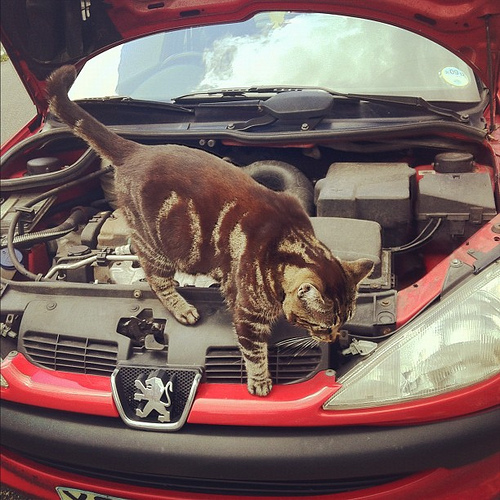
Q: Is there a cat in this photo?
A: Yes, there is a cat.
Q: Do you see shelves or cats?
A: Yes, there is a cat.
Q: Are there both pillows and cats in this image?
A: No, there is a cat but no pillows.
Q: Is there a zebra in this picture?
A: No, there are no zebras.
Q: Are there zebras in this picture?
A: No, there are no zebras.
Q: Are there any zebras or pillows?
A: No, there are no zebras or pillows.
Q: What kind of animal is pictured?
A: The animal is a cat.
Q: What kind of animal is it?
A: The animal is a cat.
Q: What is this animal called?
A: This is a cat.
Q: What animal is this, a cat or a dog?
A: This is a cat.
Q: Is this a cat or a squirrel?
A: This is a cat.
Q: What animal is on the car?
A: The animal is a cat.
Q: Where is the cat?
A: The cat is on the car.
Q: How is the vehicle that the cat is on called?
A: The vehicle is a car.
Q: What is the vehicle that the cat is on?
A: The vehicle is a car.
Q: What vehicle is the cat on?
A: The cat is on the car.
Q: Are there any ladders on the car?
A: No, there is a cat on the car.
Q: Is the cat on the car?
A: Yes, the cat is on the car.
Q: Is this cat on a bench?
A: No, the cat is on the car.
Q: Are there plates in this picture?
A: Yes, there is a plate.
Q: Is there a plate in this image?
A: Yes, there is a plate.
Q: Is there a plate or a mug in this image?
A: Yes, there is a plate.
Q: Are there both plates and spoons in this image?
A: No, there is a plate but no spoons.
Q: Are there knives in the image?
A: No, there are no knives.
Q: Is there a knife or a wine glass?
A: No, there are no knives or wine glasses.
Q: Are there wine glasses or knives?
A: No, there are no knives or wine glasses.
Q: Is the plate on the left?
A: Yes, the plate is on the left of the image.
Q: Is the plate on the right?
A: No, the plate is on the left of the image.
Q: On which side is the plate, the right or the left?
A: The plate is on the left of the image.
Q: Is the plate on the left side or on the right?
A: The plate is on the left of the image.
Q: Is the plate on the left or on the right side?
A: The plate is on the left of the image.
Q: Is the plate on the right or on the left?
A: The plate is on the left of the image.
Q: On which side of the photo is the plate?
A: The plate is on the left of the image.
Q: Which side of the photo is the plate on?
A: The plate is on the left of the image.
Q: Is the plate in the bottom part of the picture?
A: Yes, the plate is in the bottom of the image.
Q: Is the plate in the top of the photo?
A: No, the plate is in the bottom of the image.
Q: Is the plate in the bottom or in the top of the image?
A: The plate is in the bottom of the image.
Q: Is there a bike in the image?
A: No, there are no bikes.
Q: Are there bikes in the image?
A: No, there are no bikes.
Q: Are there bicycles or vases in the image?
A: No, there are no bicycles or vases.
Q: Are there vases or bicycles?
A: No, there are no bicycles or vases.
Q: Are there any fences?
A: No, there are no fences.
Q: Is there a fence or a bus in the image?
A: No, there are no fences or buses.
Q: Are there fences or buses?
A: No, there are no fences or buses.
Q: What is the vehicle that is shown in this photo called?
A: The vehicle is a car.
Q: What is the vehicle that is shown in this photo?
A: The vehicle is a car.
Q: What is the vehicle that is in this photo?
A: The vehicle is a car.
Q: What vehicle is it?
A: The vehicle is a car.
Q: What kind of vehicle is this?
A: That is a car.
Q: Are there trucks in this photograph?
A: No, there are no trucks.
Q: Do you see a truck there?
A: No, there are no trucks.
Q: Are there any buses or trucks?
A: No, there are no trucks or buses.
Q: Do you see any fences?
A: No, there are no fences.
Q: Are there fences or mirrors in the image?
A: No, there are no fences or mirrors.